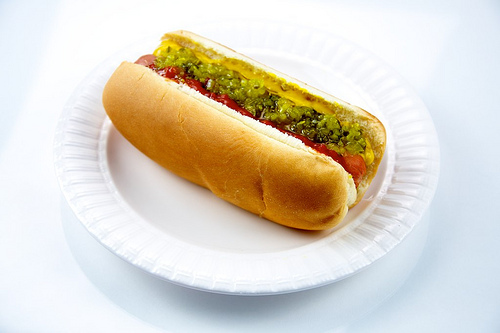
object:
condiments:
[153, 41, 376, 165]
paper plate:
[54, 14, 440, 296]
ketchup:
[159, 66, 347, 175]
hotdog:
[347, 155, 367, 184]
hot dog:
[101, 29, 385, 231]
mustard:
[151, 46, 367, 157]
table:
[0, 0, 498, 332]